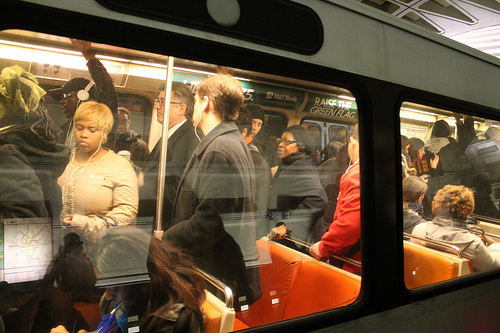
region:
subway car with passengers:
[4, 0, 499, 332]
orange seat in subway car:
[226, 237, 361, 327]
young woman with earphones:
[54, 98, 139, 246]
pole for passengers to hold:
[152, 53, 174, 255]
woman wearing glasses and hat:
[266, 122, 328, 245]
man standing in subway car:
[159, 70, 267, 310]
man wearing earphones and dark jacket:
[151, 68, 266, 308]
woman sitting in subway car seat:
[408, 184, 498, 273]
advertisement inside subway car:
[304, 91, 357, 123]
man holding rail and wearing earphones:
[43, 38, 120, 134]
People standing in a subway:
[0, 16, 499, 331]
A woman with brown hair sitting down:
[87, 229, 203, 331]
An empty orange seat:
[234, 243, 351, 330]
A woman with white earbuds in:
[66, 107, 134, 232]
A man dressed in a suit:
[152, 86, 194, 198]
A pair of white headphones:
[72, 76, 102, 103]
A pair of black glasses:
[275, 134, 298, 146]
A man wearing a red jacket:
[316, 156, 375, 278]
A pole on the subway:
[155, 54, 187, 244]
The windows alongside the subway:
[0, 31, 495, 329]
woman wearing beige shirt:
[98, 169, 113, 185]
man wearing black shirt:
[209, 176, 226, 204]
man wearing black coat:
[18, 168, 35, 198]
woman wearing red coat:
[341, 191, 359, 228]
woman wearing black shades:
[272, 135, 299, 146]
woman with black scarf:
[298, 130, 310, 144]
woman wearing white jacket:
[432, 224, 448, 241]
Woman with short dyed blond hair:
[72, 100, 112, 153]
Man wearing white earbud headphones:
[194, 95, 209, 141]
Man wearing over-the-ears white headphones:
[77, 81, 95, 99]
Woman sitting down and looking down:
[68, 225, 205, 331]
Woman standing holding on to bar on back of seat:
[270, 125, 329, 241]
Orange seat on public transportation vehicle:
[233, 243, 360, 331]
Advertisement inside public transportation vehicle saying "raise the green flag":
[302, 91, 359, 121]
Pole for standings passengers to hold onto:
[151, 57, 174, 237]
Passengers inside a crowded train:
[2, 54, 497, 326]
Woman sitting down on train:
[412, 184, 499, 276]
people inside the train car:
[3, 64, 495, 322]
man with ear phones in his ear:
[182, 69, 222, 187]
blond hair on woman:
[57, 99, 162, 235]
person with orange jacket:
[341, 130, 363, 256]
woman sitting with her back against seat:
[418, 190, 498, 285]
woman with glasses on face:
[273, 122, 292, 160]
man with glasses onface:
[137, 69, 190, 192]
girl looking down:
[93, 229, 200, 331]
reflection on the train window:
[17, 128, 267, 280]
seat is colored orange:
[259, 256, 333, 321]